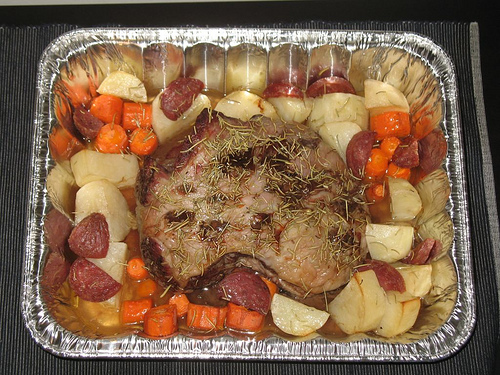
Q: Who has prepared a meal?
A: A home cook.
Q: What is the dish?
A: Pot roast.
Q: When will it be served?
A: At dinner.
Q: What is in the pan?
A: Roast and vegetables.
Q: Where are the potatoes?
A: Cut up and around the roast.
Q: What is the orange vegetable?
A: Carrots.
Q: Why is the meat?
A: Leg of Lamb.